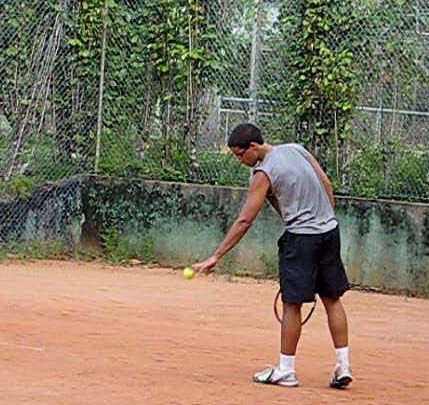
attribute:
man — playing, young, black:
[189, 122, 354, 389]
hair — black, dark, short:
[228, 122, 264, 152]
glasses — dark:
[236, 146, 249, 162]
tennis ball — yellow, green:
[184, 267, 195, 280]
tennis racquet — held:
[274, 287, 317, 327]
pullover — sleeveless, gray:
[252, 143, 340, 235]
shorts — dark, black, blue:
[278, 225, 351, 304]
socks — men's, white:
[278, 346, 351, 372]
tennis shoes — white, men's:
[252, 363, 355, 389]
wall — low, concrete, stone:
[1, 172, 429, 301]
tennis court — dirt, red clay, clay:
[1, 256, 427, 404]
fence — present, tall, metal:
[2, 2, 429, 248]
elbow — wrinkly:
[235, 218, 252, 234]